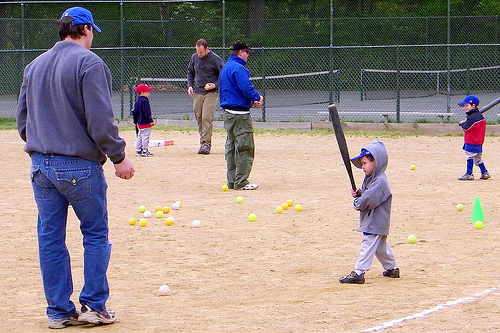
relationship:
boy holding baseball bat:
[346, 140, 402, 287] [324, 103, 365, 203]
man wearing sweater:
[183, 36, 223, 65] [182, 55, 219, 91]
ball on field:
[156, 283, 171, 296] [0, 123, 500, 333]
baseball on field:
[189, 217, 200, 227] [0, 123, 500, 333]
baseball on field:
[170, 200, 179, 210] [0, 123, 500, 333]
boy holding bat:
[337, 140, 402, 285] [326, 94, 360, 194]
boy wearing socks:
[438, 87, 499, 192] [461, 153, 491, 180]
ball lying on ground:
[245, 207, 258, 223] [0, 144, 499, 329]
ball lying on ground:
[401, 232, 417, 247] [0, 144, 499, 329]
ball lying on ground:
[155, 274, 167, 305] [0, 144, 499, 329]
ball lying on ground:
[124, 216, 139, 228] [0, 144, 499, 329]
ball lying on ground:
[229, 191, 247, 207] [0, 144, 499, 329]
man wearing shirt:
[13, 5, 138, 332] [16, 34, 142, 177]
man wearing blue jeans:
[13, 5, 138, 332] [27, 148, 118, 328]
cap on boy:
[445, 86, 497, 124] [119, 76, 162, 160]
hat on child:
[348, 147, 374, 167] [332, 107, 405, 292]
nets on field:
[128, 68, 499, 135] [3, 59, 484, 126]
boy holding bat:
[337, 140, 402, 285] [319, 99, 359, 203]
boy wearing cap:
[337, 140, 402, 285] [457, 94, 480, 107]